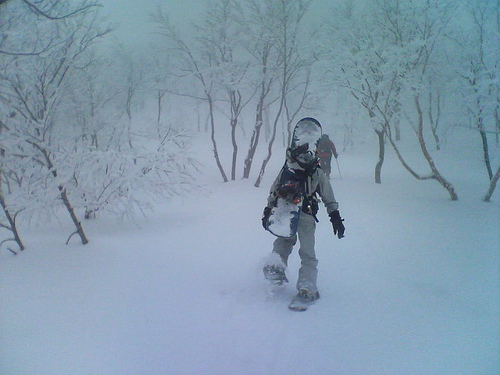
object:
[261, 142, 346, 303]
man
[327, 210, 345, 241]
gloves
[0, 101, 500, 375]
snow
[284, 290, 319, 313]
snowboard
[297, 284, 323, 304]
shoes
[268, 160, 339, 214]
coat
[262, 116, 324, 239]
snow board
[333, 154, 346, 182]
ski poles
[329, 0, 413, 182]
tree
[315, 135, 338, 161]
jacket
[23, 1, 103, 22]
branches